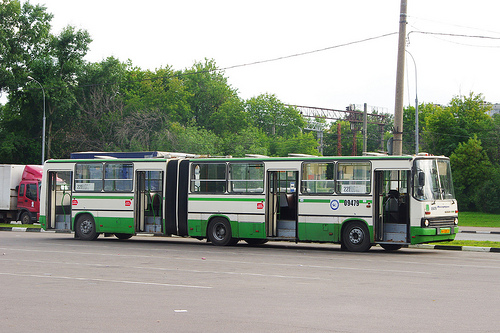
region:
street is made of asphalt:
[2, 229, 499, 326]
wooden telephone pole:
[395, 0, 407, 155]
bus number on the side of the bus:
[345, 198, 361, 208]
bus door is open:
[372, 166, 407, 244]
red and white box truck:
[0, 165, 45, 220]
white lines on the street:
[1, 270, 209, 290]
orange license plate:
[437, 228, 450, 233]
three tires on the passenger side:
[74, 213, 370, 253]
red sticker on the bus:
[256, 202, 261, 209]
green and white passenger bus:
[41, 154, 457, 248]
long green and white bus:
[35, 146, 460, 256]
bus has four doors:
[36, 149, 459, 261]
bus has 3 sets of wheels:
[58, 203, 378, 253]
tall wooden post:
[380, 0, 417, 161]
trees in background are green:
[0, 0, 499, 220]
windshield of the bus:
[408, 154, 458, 206]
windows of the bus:
[70, 162, 375, 199]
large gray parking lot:
[2, 220, 497, 330]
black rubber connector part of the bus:
[157, 155, 197, 243]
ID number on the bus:
[339, 196, 364, 208]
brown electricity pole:
[393, 0, 401, 156]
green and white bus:
[40, 158, 458, 251]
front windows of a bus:
[412, 158, 457, 200]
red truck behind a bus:
[0, 161, 67, 224]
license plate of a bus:
[439, 227, 450, 234]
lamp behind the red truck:
[26, 73, 45, 163]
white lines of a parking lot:
[5, 237, 497, 290]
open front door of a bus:
[373, 168, 410, 243]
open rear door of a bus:
[49, 168, 71, 232]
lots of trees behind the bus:
[1, 0, 318, 157]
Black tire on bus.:
[336, 208, 392, 281]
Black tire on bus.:
[206, 213, 231, 240]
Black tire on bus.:
[69, 205, 124, 265]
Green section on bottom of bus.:
[61, 203, 410, 250]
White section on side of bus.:
[61, 203, 440, 219]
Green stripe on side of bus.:
[76, 188, 413, 218]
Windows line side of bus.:
[69, 161, 436, 187]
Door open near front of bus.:
[358, 160, 429, 275]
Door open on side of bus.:
[258, 160, 310, 293]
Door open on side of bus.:
[118, 165, 178, 259]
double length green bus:
[53, 147, 413, 242]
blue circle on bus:
[329, 198, 339, 208]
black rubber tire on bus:
[348, 227, 360, 253]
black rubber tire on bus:
[199, 216, 229, 263]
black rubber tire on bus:
[82, 215, 95, 247]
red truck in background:
[0, 151, 55, 206]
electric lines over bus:
[133, 55, 322, 73]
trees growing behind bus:
[139, 70, 446, 187]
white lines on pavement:
[107, 212, 214, 319]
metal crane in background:
[264, 91, 371, 143]